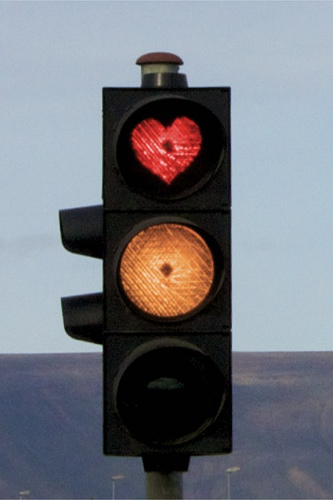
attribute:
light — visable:
[118, 78, 229, 206]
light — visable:
[88, 200, 237, 331]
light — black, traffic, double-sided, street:
[43, 20, 242, 490]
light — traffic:
[74, 35, 258, 482]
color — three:
[97, 73, 236, 208]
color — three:
[101, 193, 233, 325]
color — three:
[85, 322, 234, 458]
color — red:
[109, 90, 230, 203]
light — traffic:
[55, 42, 291, 467]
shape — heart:
[108, 92, 215, 201]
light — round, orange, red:
[106, 204, 228, 325]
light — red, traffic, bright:
[102, 65, 229, 211]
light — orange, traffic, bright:
[94, 192, 251, 342]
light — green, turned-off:
[89, 330, 247, 460]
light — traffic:
[28, 30, 296, 491]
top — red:
[109, 41, 194, 83]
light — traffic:
[39, 47, 307, 477]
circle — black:
[97, 83, 232, 208]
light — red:
[105, 88, 233, 209]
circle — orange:
[111, 214, 227, 324]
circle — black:
[106, 332, 241, 462]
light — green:
[109, 332, 231, 446]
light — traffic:
[98, 89, 236, 205]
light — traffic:
[54, 41, 239, 481]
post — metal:
[114, 462, 198, 498]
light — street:
[215, 454, 246, 496]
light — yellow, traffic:
[93, 207, 232, 323]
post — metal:
[127, 59, 189, 83]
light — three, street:
[219, 454, 252, 498]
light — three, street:
[97, 462, 139, 497]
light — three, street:
[14, 474, 28, 498]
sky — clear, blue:
[8, 8, 317, 192]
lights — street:
[43, 179, 119, 360]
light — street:
[88, 51, 235, 494]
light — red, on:
[89, 82, 238, 204]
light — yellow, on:
[99, 201, 242, 329]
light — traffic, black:
[37, 50, 256, 485]